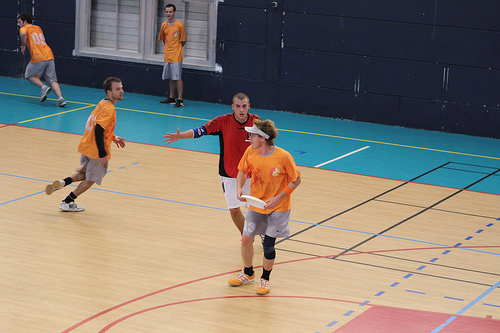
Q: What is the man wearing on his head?
A: A cap.